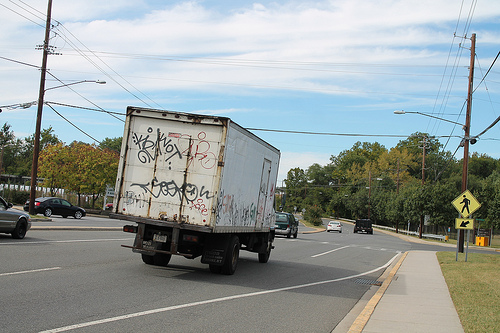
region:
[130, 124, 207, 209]
Grafitti on back of truck.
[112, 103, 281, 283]
The truck is moving.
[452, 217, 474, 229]
Black arrow on sign.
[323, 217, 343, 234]
The car in front is white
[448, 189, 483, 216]
People figure on sign.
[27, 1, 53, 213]
Electric pole is leaning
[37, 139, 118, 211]
The tree is leafy.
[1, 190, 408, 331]
The street is busy.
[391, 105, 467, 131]
The streetlight is off.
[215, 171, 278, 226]
The side of truck has grafitti.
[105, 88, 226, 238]
grafitti on back of box truck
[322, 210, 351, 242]
small white car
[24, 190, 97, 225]
black compact car turning on road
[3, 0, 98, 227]
wooden pole with power lines and street light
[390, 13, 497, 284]
wooden pole with power lines and street light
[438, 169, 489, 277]
yellow directional sign on metal pole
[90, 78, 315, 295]
large white box tuck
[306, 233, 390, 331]
white lines painted on roadway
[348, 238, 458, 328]
cement sidewalk along street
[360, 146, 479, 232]
tree with green leaves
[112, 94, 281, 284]
A commercial truck driving down the road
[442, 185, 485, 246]
Yellow sign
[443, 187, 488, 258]
A sign indicates a crosswalk.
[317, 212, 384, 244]
There are two cars ahead on the road.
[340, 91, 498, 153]
several power lines above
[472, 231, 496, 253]
Orange object on far right side.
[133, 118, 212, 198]
Someone has vandalized the truck.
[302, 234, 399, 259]
There is a crosswalk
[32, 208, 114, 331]
there are 4 lanes.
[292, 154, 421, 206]
Green trees line the street.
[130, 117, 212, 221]
white and red graffiti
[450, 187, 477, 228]
yellow and black pedestrian sign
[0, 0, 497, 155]
blue and white sky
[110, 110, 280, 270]
black and white truck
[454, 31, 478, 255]
wooden electrical posts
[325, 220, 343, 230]
white car driving forward in distance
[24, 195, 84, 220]
black car on street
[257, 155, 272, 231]
side door on white truck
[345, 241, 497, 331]
grey sidewalk next to grass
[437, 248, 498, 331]
green grass next to sidewalk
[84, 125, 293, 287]
a white truck with grafetti painted on it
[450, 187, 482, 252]
a yellow and black road sign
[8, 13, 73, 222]
a wooden electrical pole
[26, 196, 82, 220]
a black car on the roadway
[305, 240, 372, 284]
white lines painted on a roadway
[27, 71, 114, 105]
a street light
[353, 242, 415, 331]
a yellow line painted on the curb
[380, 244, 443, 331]
a concrete sidewalk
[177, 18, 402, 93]
white clouds in a blue sky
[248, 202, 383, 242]
three cars on the roadway